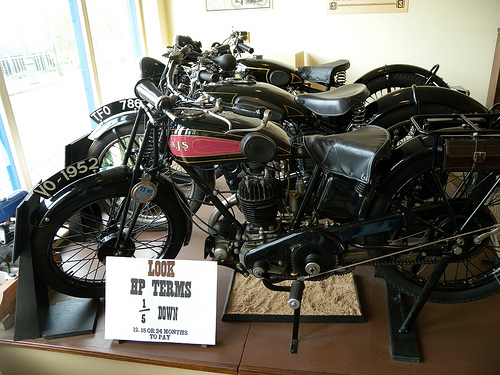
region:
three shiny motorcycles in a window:
[26, 25, 496, 365]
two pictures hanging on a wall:
[202, 1, 412, 16]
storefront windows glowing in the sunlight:
[0, 0, 152, 206]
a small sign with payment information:
[104, 255, 217, 348]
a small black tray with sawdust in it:
[218, 266, 370, 325]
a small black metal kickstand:
[288, 299, 300, 358]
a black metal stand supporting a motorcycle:
[382, 231, 464, 365]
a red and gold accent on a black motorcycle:
[166, 133, 246, 160]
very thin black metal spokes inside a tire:
[46, 192, 175, 286]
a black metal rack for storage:
[407, 110, 498, 247]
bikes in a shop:
[33, 21, 492, 317]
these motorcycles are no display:
[75, 57, 499, 283]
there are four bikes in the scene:
[94, 43, 466, 298]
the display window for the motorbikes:
[5, 8, 167, 160]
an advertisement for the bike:
[100, 251, 251, 353]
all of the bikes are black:
[90, 62, 447, 297]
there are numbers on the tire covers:
[18, 99, 138, 201]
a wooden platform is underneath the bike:
[233, 220, 376, 342]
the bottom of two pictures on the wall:
[199, 1, 416, 26]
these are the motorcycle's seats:
[298, 46, 395, 197]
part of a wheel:
[466, 285, 469, 288]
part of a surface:
[258, 348, 269, 360]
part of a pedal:
[286, 283, 300, 295]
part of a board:
[164, 298, 191, 324]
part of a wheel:
[51, 223, 75, 247]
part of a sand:
[313, 296, 342, 326]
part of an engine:
[258, 214, 267, 217]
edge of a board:
[209, 279, 213, 296]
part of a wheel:
[391, 288, 423, 315]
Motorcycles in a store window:
[20, 41, 497, 319]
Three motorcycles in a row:
[37, 29, 498, 346]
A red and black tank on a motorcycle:
[169, 100, 292, 169]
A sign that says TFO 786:
[90, 97, 142, 121]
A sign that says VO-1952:
[23, 157, 112, 198]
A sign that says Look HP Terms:
[124, 260, 198, 297]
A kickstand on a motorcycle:
[289, 305, 304, 360]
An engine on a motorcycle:
[202, 158, 318, 238]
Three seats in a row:
[295, 51, 402, 202]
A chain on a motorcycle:
[338, 249, 442, 274]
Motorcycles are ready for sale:
[8, 25, 498, 365]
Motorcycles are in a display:
[12, 28, 487, 373]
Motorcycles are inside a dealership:
[16, 16, 488, 361]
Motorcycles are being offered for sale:
[20, 25, 495, 373]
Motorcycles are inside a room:
[21, 25, 488, 373]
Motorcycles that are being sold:
[20, 22, 485, 365]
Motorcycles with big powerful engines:
[15, 30, 486, 360]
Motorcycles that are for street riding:
[15, 16, 488, 371]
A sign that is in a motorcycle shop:
[103, 260, 215, 340]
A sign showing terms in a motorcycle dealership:
[106, 260, 218, 342]